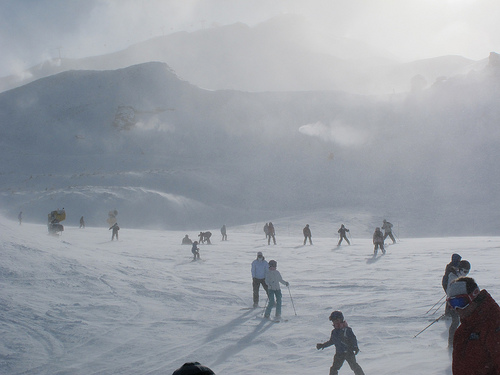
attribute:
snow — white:
[271, 50, 298, 104]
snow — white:
[1, 15, 497, 372]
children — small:
[181, 234, 209, 261]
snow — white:
[103, 8, 161, 67]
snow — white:
[0, 211, 497, 373]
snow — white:
[8, 175, 205, 206]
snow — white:
[16, 67, 69, 77]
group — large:
[3, 201, 404, 314]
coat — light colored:
[264, 270, 286, 292]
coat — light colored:
[252, 258, 268, 282]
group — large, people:
[36, 196, 476, 356]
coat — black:
[451, 288, 485, 373]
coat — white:
[264, 267, 290, 287]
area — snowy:
[4, 217, 498, 373]